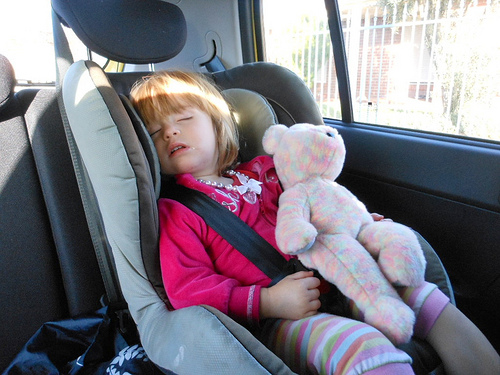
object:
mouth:
[166, 142, 190, 158]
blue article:
[0, 316, 133, 374]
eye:
[175, 114, 194, 123]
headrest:
[113, 85, 277, 201]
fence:
[291, 0, 499, 142]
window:
[257, 0, 344, 124]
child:
[126, 66, 498, 375]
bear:
[261, 121, 426, 349]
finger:
[301, 277, 321, 287]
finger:
[306, 289, 320, 298]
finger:
[308, 299, 320, 309]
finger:
[303, 310, 319, 319]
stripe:
[347, 352, 412, 375]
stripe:
[324, 325, 381, 374]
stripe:
[409, 287, 449, 344]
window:
[334, 0, 498, 143]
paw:
[274, 216, 320, 259]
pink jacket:
[158, 153, 293, 316]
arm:
[157, 196, 267, 326]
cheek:
[186, 125, 217, 159]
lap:
[316, 315, 391, 359]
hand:
[263, 269, 321, 321]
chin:
[173, 153, 197, 175]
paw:
[376, 247, 427, 291]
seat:
[0, 51, 163, 374]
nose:
[158, 119, 182, 142]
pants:
[255, 280, 450, 374]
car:
[0, 0, 498, 374]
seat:
[49, 0, 458, 374]